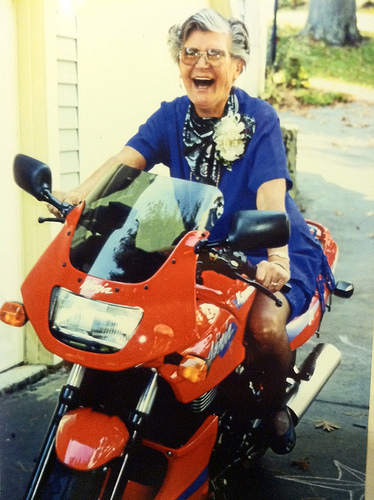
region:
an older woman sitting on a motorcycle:
[10, 8, 351, 474]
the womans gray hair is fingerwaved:
[162, 5, 250, 71]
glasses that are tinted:
[177, 43, 230, 66]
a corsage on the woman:
[206, 111, 249, 162]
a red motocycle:
[1, 152, 349, 497]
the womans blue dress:
[123, 86, 335, 323]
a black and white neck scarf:
[177, 92, 248, 193]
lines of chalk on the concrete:
[274, 455, 366, 498]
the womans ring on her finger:
[269, 278, 283, 288]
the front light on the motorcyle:
[44, 283, 147, 363]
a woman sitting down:
[41, 4, 324, 445]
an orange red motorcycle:
[9, 198, 347, 493]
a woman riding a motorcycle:
[13, 14, 344, 498]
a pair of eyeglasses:
[176, 43, 228, 65]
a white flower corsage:
[211, 112, 253, 167]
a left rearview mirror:
[227, 206, 287, 249]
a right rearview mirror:
[7, 151, 82, 223]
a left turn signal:
[173, 346, 208, 385]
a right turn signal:
[0, 298, 25, 331]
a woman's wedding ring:
[269, 277, 280, 286]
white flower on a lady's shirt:
[165, 90, 262, 185]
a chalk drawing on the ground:
[266, 447, 366, 498]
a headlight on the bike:
[38, 262, 159, 386]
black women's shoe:
[251, 384, 315, 468]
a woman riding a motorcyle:
[36, 11, 356, 436]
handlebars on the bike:
[4, 146, 312, 319]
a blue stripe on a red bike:
[169, 438, 256, 498]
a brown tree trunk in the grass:
[291, 0, 365, 65]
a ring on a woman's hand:
[265, 274, 283, 291]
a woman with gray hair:
[145, 5, 256, 133]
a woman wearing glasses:
[149, 4, 263, 137]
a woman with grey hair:
[161, 8, 280, 130]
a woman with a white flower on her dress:
[149, 11, 296, 207]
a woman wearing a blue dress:
[121, 24, 303, 255]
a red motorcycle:
[26, 176, 331, 444]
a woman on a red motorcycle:
[1, 10, 333, 431]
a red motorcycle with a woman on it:
[25, 33, 350, 446]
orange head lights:
[9, 285, 253, 402]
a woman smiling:
[153, 4, 288, 216]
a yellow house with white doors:
[16, 3, 345, 443]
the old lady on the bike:
[39, 11, 328, 452]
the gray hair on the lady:
[168, 5, 247, 58]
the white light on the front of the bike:
[47, 281, 144, 349]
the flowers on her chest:
[213, 113, 242, 162]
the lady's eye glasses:
[179, 42, 229, 66]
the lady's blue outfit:
[127, 89, 331, 310]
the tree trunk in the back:
[302, 0, 359, 43]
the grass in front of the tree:
[306, 43, 372, 70]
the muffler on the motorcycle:
[288, 342, 344, 415]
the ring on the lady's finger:
[268, 278, 277, 286]